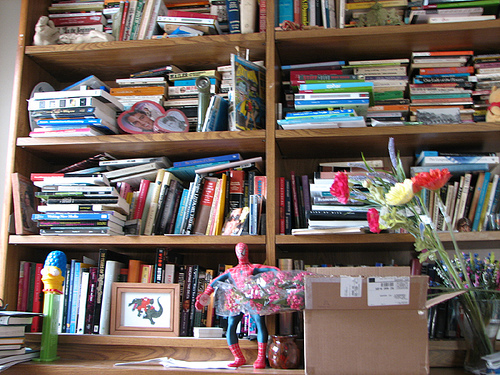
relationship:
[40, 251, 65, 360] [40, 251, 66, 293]
character has head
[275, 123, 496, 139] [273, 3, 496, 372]
shelf a piece of case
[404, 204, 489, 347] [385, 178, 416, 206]
stem for flower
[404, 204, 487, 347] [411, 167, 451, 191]
stem for flower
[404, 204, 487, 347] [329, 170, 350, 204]
stem for flower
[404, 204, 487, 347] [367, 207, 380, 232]
stem for flower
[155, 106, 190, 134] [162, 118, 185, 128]
frame has image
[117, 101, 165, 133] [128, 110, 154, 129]
frame has image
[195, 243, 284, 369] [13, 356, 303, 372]
man on top of shelf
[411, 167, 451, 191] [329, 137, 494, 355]
flower part of bouquet group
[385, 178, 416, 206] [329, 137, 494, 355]
flower part of bouquet group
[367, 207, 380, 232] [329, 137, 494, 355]
flower part of bouquet group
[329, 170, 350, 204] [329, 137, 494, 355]
flower part of bouquet group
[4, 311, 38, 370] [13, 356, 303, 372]
pile on top of shelf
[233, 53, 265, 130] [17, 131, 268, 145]
book sticking out of shelf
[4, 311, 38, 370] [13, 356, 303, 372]
pile on top of a shelf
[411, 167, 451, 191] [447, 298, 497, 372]
flower inside a vase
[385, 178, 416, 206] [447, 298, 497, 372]
flower inside a vase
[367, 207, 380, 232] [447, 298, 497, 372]
flower inside a vase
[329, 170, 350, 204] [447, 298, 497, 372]
flower inside a vase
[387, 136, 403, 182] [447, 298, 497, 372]
flower inside a vase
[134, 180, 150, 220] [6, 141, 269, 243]
book on top of shelf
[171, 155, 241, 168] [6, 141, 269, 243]
book on top of shelf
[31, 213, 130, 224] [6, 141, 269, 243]
book on top of shelf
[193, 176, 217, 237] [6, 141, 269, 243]
book on top of shelf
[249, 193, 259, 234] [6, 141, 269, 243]
book on top of shelf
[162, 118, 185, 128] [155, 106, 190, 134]
image inside frame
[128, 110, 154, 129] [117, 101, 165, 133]
image inside frame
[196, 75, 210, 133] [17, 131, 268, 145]
flashlight on top of shelf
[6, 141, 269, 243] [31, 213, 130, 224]
shelf has a book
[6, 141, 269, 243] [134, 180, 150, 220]
shelf has a book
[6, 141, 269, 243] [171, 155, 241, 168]
shelf has a book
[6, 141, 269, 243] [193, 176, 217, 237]
shelf has a book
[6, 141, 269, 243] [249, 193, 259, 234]
shelf has a book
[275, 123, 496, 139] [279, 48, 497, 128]
shelf holding stacked books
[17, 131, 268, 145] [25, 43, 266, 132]
shelf holding stacked books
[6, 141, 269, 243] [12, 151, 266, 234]
shelf holding stacked books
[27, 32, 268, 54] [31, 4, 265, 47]
shelf holding stacked books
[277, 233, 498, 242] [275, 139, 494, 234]
shelf holding stacked books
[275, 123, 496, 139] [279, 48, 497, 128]
shelf filled with stacked books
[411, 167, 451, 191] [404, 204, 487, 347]
flower at end of a stem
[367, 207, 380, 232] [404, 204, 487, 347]
flower at end of a stem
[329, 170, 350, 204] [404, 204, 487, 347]
flower at end of a stem